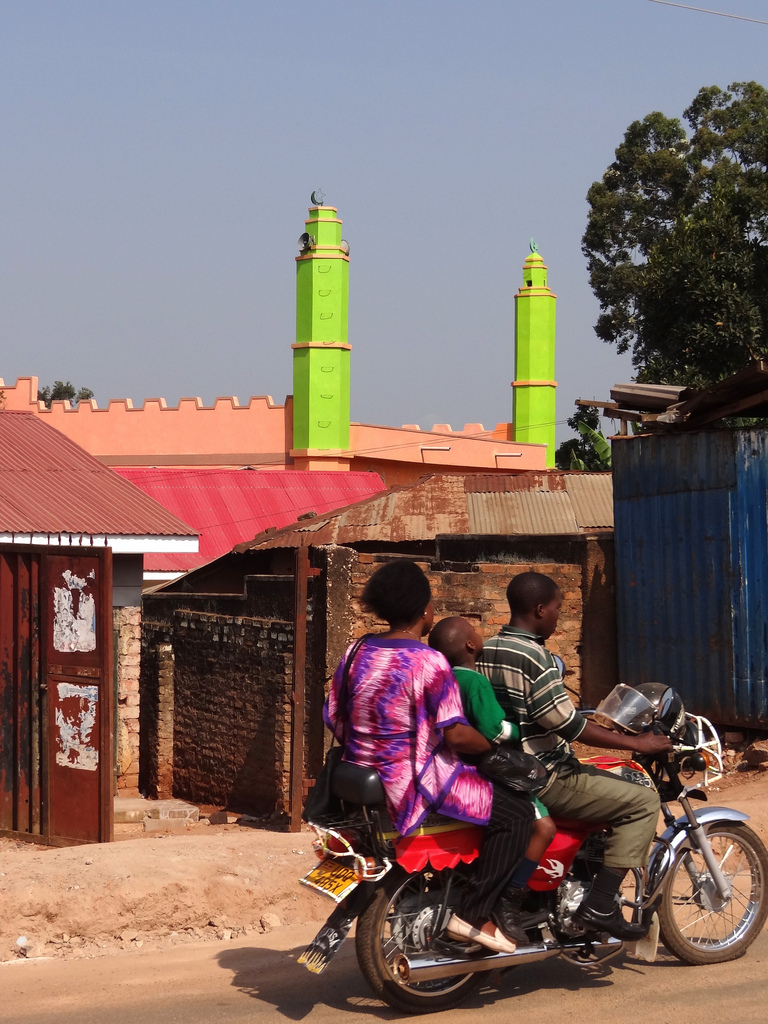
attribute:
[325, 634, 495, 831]
shirt — pink, purple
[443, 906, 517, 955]
loafer — white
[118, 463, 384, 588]
red roof — bright red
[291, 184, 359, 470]
tower — tall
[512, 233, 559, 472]
tower — tall, green , gold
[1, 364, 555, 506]
building — pink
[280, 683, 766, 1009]
motorcycle — red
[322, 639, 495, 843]
dress — purple , white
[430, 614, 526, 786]
boy — little 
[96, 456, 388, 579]
roof — red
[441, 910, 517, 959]
shoe — white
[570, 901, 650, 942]
shoe — black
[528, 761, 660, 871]
pants — brown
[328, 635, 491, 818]
shirt — purple, Pink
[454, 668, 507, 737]
shirt — green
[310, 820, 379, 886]
light — back light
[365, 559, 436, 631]
hair — black